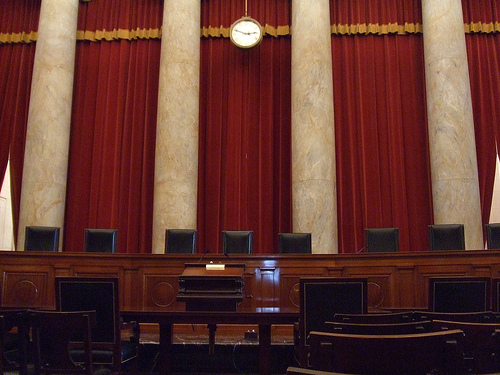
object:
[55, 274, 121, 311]
chair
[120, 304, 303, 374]
desk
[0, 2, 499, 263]
curtain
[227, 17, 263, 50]
clock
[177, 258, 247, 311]
podium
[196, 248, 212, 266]
microphone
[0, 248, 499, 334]
desk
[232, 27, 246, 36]
clock hand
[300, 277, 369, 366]
chair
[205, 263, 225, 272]
paper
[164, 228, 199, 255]
seat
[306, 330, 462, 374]
seat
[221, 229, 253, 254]
chair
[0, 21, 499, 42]
trim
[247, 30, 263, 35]
clock hand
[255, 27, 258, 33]
2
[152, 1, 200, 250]
pillar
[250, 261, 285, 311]
reflection